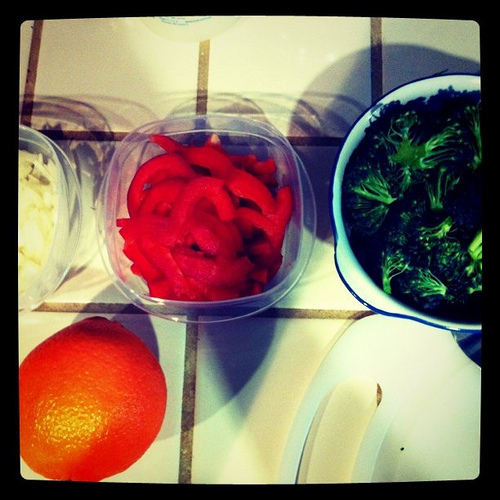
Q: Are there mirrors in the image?
A: No, there are no mirrors.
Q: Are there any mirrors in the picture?
A: No, there are no mirrors.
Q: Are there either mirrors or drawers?
A: No, there are no mirrors or drawers.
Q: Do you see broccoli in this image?
A: Yes, there is broccoli.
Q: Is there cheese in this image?
A: No, there is no cheese.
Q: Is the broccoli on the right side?
A: Yes, the broccoli is on the right of the image.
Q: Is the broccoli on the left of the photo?
A: No, the broccoli is on the right of the image.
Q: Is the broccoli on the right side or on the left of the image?
A: The broccoli is on the right of the image.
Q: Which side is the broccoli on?
A: The broccoli is on the right of the image.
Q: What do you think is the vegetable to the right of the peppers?
A: The vegetable is broccoli.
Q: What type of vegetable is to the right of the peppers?
A: The vegetable is broccoli.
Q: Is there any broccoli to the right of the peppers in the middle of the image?
A: Yes, there is broccoli to the right of the peppers.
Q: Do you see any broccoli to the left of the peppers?
A: No, the broccoli is to the right of the peppers.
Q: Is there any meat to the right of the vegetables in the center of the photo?
A: No, there is broccoli to the right of the peppers.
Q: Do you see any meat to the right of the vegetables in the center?
A: No, there is broccoli to the right of the peppers.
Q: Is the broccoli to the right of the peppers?
A: Yes, the broccoli is to the right of the peppers.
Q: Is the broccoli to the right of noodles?
A: No, the broccoli is to the right of the peppers.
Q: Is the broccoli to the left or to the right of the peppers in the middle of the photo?
A: The broccoli is to the right of the peppers.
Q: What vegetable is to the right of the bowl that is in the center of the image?
A: The vegetable is broccoli.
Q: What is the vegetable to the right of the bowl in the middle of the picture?
A: The vegetable is broccoli.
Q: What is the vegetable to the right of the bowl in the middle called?
A: The vegetable is broccoli.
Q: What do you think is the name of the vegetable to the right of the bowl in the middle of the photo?
A: The vegetable is broccoli.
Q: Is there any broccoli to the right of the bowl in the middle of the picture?
A: Yes, there is broccoli to the right of the bowl.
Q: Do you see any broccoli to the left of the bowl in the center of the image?
A: No, the broccoli is to the right of the bowl.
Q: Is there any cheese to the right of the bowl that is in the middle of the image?
A: No, there is broccoli to the right of the bowl.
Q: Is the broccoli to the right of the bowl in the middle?
A: Yes, the broccoli is to the right of the bowl.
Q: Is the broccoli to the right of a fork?
A: No, the broccoli is to the right of the bowl.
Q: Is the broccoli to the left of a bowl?
A: No, the broccoli is to the right of a bowl.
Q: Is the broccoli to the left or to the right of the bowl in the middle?
A: The broccoli is to the right of the bowl.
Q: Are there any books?
A: No, there are no books.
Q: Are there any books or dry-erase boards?
A: No, there are no books or dry-erase boards.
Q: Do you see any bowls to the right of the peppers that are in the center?
A: Yes, there is a bowl to the right of the peppers.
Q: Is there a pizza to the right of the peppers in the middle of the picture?
A: No, there is a bowl to the right of the peppers.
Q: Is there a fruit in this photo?
A: Yes, there is a fruit.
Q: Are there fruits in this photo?
A: Yes, there is a fruit.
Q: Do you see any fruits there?
A: Yes, there is a fruit.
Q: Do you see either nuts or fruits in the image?
A: Yes, there is a fruit.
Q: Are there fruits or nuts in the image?
A: Yes, there is a fruit.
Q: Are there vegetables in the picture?
A: Yes, there are vegetables.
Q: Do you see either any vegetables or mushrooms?
A: Yes, there are vegetables.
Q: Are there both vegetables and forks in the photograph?
A: No, there are vegetables but no forks.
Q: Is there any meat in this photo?
A: No, there is no meat.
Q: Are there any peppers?
A: Yes, there are peppers.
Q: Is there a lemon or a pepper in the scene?
A: Yes, there are peppers.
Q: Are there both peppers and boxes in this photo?
A: No, there are peppers but no boxes.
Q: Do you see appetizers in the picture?
A: No, there are no appetizers.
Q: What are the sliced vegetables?
A: The vegetables are peppers.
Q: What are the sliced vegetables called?
A: The vegetables are peppers.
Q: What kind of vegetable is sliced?
A: The vegetable is peppers.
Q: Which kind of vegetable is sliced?
A: The vegetable is peppers.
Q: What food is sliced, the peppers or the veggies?
A: The peppers is sliced.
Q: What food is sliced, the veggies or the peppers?
A: The peppers is sliced.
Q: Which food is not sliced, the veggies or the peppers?
A: The veggies is not sliced.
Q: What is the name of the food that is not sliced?
A: The food is vegetables.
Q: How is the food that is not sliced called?
A: The food is vegetables.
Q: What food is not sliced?
A: The food is vegetables.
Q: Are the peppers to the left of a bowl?
A: Yes, the peppers are to the left of a bowl.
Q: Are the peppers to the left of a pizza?
A: No, the peppers are to the left of a bowl.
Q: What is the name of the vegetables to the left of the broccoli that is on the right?
A: The vegetables are peppers.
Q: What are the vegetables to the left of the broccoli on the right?
A: The vegetables are peppers.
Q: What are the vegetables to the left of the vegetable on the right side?
A: The vegetables are peppers.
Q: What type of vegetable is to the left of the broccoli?
A: The vegetables are peppers.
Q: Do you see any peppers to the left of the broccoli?
A: Yes, there are peppers to the left of the broccoli.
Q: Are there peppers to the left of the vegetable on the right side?
A: Yes, there are peppers to the left of the broccoli.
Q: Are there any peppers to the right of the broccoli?
A: No, the peppers are to the left of the broccoli.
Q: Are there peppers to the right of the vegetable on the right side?
A: No, the peppers are to the left of the broccoli.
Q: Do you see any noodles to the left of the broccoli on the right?
A: No, there are peppers to the left of the broccoli.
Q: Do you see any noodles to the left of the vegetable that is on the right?
A: No, there are peppers to the left of the broccoli.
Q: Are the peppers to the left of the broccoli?
A: Yes, the peppers are to the left of the broccoli.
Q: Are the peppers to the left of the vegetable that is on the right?
A: Yes, the peppers are to the left of the broccoli.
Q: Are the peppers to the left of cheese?
A: No, the peppers are to the left of the broccoli.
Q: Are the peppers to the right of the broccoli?
A: No, the peppers are to the left of the broccoli.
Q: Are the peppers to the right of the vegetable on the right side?
A: No, the peppers are to the left of the broccoli.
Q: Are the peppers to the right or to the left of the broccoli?
A: The peppers are to the left of the broccoli.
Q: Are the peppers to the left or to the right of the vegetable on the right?
A: The peppers are to the left of the broccoli.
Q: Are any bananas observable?
A: Yes, there is a banana.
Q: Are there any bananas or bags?
A: Yes, there is a banana.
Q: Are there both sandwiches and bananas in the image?
A: No, there is a banana but no sandwiches.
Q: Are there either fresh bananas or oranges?
A: Yes, there is a fresh banana.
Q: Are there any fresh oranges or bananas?
A: Yes, there is a fresh banana.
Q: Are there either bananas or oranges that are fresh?
A: Yes, the banana is fresh.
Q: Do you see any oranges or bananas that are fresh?
A: Yes, the banana is fresh.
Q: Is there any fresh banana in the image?
A: Yes, there is a fresh banana.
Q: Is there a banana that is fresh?
A: Yes, there is a banana that is fresh.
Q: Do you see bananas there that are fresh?
A: Yes, there is a banana that is fresh.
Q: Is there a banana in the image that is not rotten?
A: Yes, there is a fresh banana.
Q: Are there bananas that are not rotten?
A: Yes, there is a fresh banana.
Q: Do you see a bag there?
A: No, there are no bags.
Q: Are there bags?
A: No, there are no bags.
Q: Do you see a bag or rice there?
A: No, there are no bags or rice.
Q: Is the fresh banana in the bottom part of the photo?
A: Yes, the banana is in the bottom of the image.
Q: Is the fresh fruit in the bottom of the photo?
A: Yes, the banana is in the bottom of the image.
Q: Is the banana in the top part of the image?
A: No, the banana is in the bottom of the image.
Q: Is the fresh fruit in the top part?
A: No, the banana is in the bottom of the image.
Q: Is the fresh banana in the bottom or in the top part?
A: The banana is in the bottom of the image.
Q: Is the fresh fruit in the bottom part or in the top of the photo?
A: The banana is in the bottom of the image.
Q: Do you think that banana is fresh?
A: Yes, the banana is fresh.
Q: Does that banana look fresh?
A: Yes, the banana is fresh.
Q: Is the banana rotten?
A: No, the banana is fresh.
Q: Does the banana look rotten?
A: No, the banana is fresh.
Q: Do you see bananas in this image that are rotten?
A: No, there is a banana but it is fresh.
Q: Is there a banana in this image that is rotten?
A: No, there is a banana but it is fresh.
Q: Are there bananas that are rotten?
A: No, there is a banana but it is fresh.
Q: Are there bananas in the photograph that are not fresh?
A: No, there is a banana but it is fresh.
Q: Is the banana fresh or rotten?
A: The banana is fresh.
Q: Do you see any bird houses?
A: No, there are no bird houses.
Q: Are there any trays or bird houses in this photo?
A: No, there are no bird houses or trays.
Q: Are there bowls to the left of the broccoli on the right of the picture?
A: Yes, there is a bowl to the left of the broccoli.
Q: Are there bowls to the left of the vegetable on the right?
A: Yes, there is a bowl to the left of the broccoli.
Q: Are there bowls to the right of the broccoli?
A: No, the bowl is to the left of the broccoli.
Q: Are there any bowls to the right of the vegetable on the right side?
A: No, the bowl is to the left of the broccoli.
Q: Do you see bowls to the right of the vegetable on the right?
A: No, the bowl is to the left of the broccoli.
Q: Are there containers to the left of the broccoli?
A: No, there is a bowl to the left of the broccoli.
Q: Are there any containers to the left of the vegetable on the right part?
A: No, there is a bowl to the left of the broccoli.